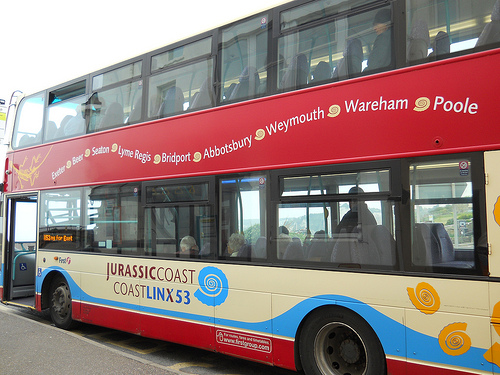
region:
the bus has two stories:
[15, 7, 465, 232]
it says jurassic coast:
[80, 249, 217, 305]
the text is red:
[102, 260, 197, 281]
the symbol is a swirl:
[189, 250, 249, 307]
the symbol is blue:
[187, 256, 239, 309]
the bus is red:
[5, 64, 447, 199]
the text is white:
[30, 74, 492, 223]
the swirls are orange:
[397, 281, 472, 371]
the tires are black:
[307, 310, 374, 362]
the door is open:
[0, 189, 53, 320]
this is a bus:
[15, 0, 495, 372]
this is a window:
[41, 75, 88, 137]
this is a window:
[80, 68, 150, 128]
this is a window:
[151, 29, 211, 116]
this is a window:
[221, 18, 279, 103]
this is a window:
[278, 0, 350, 84]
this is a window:
[271, 169, 392, 269]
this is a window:
[405, 158, 482, 270]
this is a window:
[80, 189, 141, 251]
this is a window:
[142, 179, 213, 263]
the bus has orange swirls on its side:
[407, 280, 440, 317]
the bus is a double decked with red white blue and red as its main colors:
[8, 1, 497, 373]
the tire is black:
[48, 273, 73, 330]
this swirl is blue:
[193, 265, 232, 310]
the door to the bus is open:
[8, 189, 44, 312]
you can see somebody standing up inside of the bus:
[338, 186, 375, 227]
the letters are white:
[342, 95, 412, 113]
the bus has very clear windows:
[38, 148, 491, 275]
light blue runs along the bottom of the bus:
[35, 267, 497, 363]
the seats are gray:
[408, 215, 465, 268]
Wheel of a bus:
[32, 263, 83, 335]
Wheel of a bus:
[286, 302, 388, 373]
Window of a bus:
[219, 177, 274, 265]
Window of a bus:
[272, 159, 403, 198]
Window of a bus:
[273, 200, 397, 267]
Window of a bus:
[404, 156, 474, 201]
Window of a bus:
[405, 197, 478, 272]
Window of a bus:
[138, 178, 213, 202]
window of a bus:
[6, 95, 54, 169]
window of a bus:
[26, 188, 100, 259]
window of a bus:
[75, 178, 149, 253]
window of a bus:
[142, 162, 226, 266]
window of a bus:
[215, 143, 272, 275]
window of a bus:
[255, 139, 417, 269]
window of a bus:
[376, 149, 497, 317]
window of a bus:
[386, 0, 496, 52]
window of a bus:
[275, 0, 396, 62]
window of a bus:
[196, 0, 266, 108]